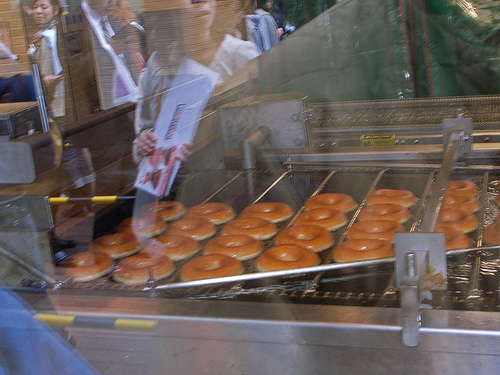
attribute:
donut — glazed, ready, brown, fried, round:
[178, 254, 243, 284]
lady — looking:
[132, 0, 280, 182]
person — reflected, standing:
[31, 2, 69, 126]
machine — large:
[4, 96, 499, 375]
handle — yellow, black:
[35, 312, 157, 334]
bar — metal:
[409, 128, 463, 234]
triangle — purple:
[111, 67, 134, 106]